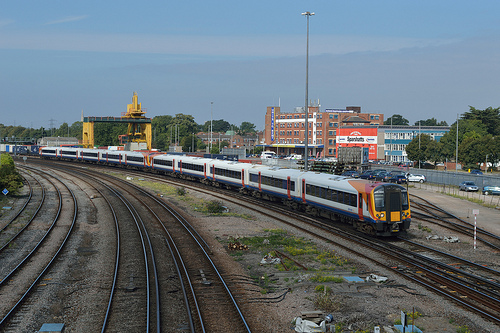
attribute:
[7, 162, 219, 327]
tracks — in rows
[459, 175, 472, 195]
car — silver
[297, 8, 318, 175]
post — tall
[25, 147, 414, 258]
train — yellow, moving, long, white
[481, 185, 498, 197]
vehicle — parked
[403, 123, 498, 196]
trees — green, clustered, large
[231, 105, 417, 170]
buildings — in background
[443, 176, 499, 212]
cars — parked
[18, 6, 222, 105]
sky — blue, clear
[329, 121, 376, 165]
sign — red, large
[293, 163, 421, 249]
engine — white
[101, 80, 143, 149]
crane — large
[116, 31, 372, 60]
clouds — white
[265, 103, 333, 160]
house — large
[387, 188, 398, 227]
door — shut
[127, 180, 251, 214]
grass — scattered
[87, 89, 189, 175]
tower — green